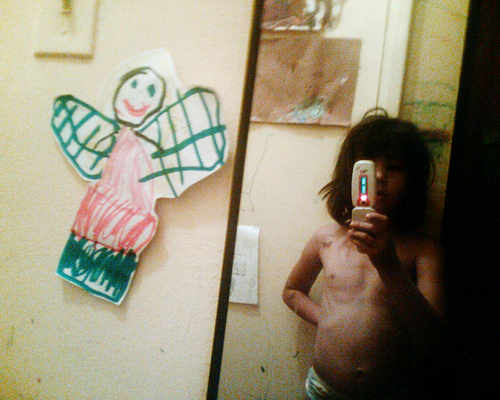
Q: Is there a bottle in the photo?
A: No, there are no bottles.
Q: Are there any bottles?
A: No, there are no bottles.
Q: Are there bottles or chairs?
A: No, there are no bottles or chairs.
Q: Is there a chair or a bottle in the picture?
A: No, there are no bottles or chairs.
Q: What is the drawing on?
A: The drawing is on the wall.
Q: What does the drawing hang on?
A: The drawing hangs on the wall.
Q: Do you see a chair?
A: No, there are no chairs.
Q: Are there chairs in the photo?
A: No, there are no chairs.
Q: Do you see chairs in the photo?
A: No, there are no chairs.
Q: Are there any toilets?
A: No, there are no toilets.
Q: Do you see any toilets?
A: No, there are no toilets.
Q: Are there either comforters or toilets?
A: No, there are no toilets or comforters.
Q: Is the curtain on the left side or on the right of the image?
A: The curtain is on the right of the image.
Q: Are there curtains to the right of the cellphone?
A: Yes, there is a curtain to the right of the cellphone.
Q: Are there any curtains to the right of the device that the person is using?
A: Yes, there is a curtain to the right of the cellphone.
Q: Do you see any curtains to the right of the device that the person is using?
A: Yes, there is a curtain to the right of the cellphone.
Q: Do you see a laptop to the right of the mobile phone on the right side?
A: No, there is a curtain to the right of the mobile phone.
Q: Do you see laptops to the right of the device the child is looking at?
A: No, there is a curtain to the right of the mobile phone.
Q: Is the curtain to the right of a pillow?
A: No, the curtain is to the right of the cellphone.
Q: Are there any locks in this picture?
A: No, there are no locks.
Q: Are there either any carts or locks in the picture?
A: No, there are no locks or carts.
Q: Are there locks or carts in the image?
A: No, there are no locks or carts.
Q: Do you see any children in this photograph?
A: Yes, there is a child.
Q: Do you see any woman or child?
A: Yes, there is a child.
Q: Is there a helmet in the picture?
A: No, there are no helmets.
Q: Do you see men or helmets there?
A: No, there are no helmets or men.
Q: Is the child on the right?
A: Yes, the child is on the right of the image.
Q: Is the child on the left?
A: No, the child is on the right of the image.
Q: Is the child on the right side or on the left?
A: The child is on the right of the image.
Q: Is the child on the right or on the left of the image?
A: The child is on the right of the image.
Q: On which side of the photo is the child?
A: The child is on the right of the image.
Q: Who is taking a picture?
A: The kid is taking a picture.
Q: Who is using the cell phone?
A: The child is using the cell phone.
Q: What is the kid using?
A: The kid is using a cell phone.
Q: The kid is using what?
A: The kid is using a cell phone.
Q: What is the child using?
A: The kid is using a cell phone.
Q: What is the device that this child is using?
A: The device is a cell phone.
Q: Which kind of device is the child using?
A: The child is using a cell phone.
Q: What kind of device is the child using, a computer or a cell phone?
A: The child is using a cell phone.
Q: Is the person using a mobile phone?
A: Yes, the kid is using a mobile phone.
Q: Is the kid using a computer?
A: No, the kid is using a mobile phone.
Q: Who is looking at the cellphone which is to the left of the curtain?
A: The child is looking at the mobile phone.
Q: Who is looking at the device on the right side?
A: The child is looking at the mobile phone.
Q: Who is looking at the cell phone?
A: The child is looking at the mobile phone.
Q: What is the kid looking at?
A: The kid is looking at the cellphone.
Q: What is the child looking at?
A: The kid is looking at the cellphone.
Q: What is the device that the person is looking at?
A: The device is a cell phone.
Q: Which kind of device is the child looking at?
A: The child is looking at the mobile phone.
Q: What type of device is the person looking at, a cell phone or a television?
A: The child is looking at a cell phone.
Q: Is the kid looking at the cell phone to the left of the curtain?
A: Yes, the kid is looking at the mobile phone.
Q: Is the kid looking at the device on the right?
A: Yes, the kid is looking at the mobile phone.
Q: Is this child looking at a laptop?
A: No, the child is looking at the mobile phone.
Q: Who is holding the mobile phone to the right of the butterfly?
A: The kid is holding the mobile phone.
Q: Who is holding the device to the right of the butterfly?
A: The kid is holding the mobile phone.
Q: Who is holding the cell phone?
A: The kid is holding the mobile phone.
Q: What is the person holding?
A: The child is holding the mobile phone.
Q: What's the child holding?
A: The child is holding the mobile phone.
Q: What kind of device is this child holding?
A: The child is holding the cell phone.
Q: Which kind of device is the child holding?
A: The child is holding the cell phone.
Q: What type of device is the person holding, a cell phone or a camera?
A: The kid is holding a cell phone.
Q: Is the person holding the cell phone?
A: Yes, the kid is holding the cell phone.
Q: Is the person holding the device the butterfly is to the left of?
A: Yes, the kid is holding the cell phone.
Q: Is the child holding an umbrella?
A: No, the child is holding the cell phone.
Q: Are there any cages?
A: No, there are no cages.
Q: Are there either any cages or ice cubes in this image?
A: No, there are no cages or ice cubes.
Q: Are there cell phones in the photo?
A: Yes, there is a cell phone.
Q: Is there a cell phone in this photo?
A: Yes, there is a cell phone.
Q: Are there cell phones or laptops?
A: Yes, there is a cell phone.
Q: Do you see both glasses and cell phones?
A: No, there is a cell phone but no glasses.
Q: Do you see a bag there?
A: No, there are no bags.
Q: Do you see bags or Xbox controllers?
A: No, there are no bags or Xbox controllers.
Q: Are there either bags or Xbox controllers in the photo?
A: No, there are no bags or Xbox controllers.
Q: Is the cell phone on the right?
A: Yes, the cell phone is on the right of the image.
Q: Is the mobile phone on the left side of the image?
A: No, the mobile phone is on the right of the image.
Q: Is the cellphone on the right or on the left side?
A: The cellphone is on the right of the image.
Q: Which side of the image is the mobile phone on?
A: The mobile phone is on the right of the image.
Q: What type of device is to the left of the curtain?
A: The device is a cell phone.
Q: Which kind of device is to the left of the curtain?
A: The device is a cell phone.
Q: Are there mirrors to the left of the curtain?
A: No, there is a cell phone to the left of the curtain.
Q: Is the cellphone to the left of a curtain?
A: Yes, the cellphone is to the left of a curtain.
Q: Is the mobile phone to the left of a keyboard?
A: No, the mobile phone is to the left of a curtain.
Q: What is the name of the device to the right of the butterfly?
A: The device is a cell phone.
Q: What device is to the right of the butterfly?
A: The device is a cell phone.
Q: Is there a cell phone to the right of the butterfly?
A: Yes, there is a cell phone to the right of the butterfly.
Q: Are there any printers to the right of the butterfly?
A: No, there is a cell phone to the right of the butterfly.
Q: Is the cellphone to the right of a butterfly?
A: Yes, the cellphone is to the right of a butterfly.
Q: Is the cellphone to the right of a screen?
A: No, the cellphone is to the right of a butterfly.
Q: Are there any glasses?
A: No, there are no glasses.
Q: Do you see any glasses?
A: No, there are no glasses.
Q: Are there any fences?
A: No, there are no fences.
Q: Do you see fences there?
A: No, there are no fences.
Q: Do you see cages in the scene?
A: No, there are no cages.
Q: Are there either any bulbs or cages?
A: No, there are no cages or bulbs.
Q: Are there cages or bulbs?
A: No, there are no cages or bulbs.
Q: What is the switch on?
A: The switch is on the wall.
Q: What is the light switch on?
A: The switch is on the wall.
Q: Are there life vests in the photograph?
A: No, there are no life vests.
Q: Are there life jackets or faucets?
A: No, there are no life jackets or faucets.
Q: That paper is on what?
A: The paper is on the wall.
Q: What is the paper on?
A: The paper is on the wall.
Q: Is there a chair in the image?
A: No, there are no chairs.